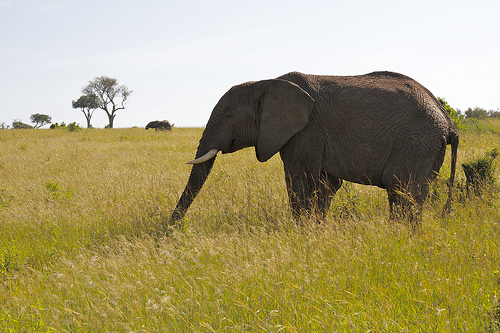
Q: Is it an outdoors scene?
A: Yes, it is outdoors.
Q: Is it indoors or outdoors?
A: It is outdoors.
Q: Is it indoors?
A: No, it is outdoors.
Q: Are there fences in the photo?
A: No, there are no fences.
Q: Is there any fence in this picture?
A: No, there are no fences.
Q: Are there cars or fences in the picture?
A: No, there are no fences or cars.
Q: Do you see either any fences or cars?
A: No, there are no fences or cars.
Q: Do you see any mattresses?
A: No, there are no mattresses.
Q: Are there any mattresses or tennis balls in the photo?
A: No, there are no mattresses or tennis balls.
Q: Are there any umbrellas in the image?
A: No, there are no umbrellas.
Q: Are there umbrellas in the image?
A: No, there are no umbrellas.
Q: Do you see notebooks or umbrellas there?
A: No, there are no umbrellas or notebooks.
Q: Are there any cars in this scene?
A: No, there are no cars.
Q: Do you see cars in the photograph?
A: No, there are no cars.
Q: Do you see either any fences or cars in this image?
A: No, there are no cars or fences.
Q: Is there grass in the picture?
A: Yes, there is grass.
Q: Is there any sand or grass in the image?
A: Yes, there is grass.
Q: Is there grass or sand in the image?
A: Yes, there is grass.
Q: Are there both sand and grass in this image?
A: No, there is grass but no sand.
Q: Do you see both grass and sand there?
A: No, there is grass but no sand.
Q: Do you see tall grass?
A: Yes, there is tall grass.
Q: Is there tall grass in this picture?
A: Yes, there is tall grass.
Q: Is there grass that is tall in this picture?
A: Yes, there is tall grass.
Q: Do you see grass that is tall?
A: Yes, there is grass that is tall.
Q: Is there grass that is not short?
A: Yes, there is tall grass.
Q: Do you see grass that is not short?
A: Yes, there is tall grass.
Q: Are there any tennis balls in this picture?
A: No, there are no tennis balls.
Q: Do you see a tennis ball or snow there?
A: No, there are no tennis balls or snow.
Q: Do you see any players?
A: No, there are no players.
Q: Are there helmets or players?
A: No, there are no players or helmets.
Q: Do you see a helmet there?
A: No, there are no helmets.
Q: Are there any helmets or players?
A: No, there are no helmets or players.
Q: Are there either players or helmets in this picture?
A: No, there are no helmets or players.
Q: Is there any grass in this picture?
A: Yes, there is grass.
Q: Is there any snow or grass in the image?
A: Yes, there is grass.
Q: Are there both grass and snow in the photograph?
A: No, there is grass but no snow.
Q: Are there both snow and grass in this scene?
A: No, there is grass but no snow.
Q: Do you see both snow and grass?
A: No, there is grass but no snow.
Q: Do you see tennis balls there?
A: No, there are no tennis balls.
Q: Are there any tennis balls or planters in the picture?
A: No, there are no tennis balls or planters.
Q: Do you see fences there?
A: No, there are no fences.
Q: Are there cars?
A: No, there are no cars.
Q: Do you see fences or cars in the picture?
A: No, there are no cars or fences.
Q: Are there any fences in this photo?
A: No, there are no fences.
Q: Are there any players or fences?
A: No, there are no fences or players.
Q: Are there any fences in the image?
A: No, there are no fences.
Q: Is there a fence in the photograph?
A: No, there are no fences.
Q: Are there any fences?
A: No, there are no fences.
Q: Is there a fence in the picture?
A: No, there are no fences.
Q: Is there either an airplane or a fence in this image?
A: No, there are no fences or airplanes.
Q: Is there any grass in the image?
A: Yes, there is grass.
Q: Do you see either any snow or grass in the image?
A: Yes, there is grass.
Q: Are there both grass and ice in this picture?
A: No, there is grass but no ice.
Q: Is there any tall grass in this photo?
A: Yes, there is tall grass.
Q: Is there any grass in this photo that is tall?
A: Yes, there is grass that is tall.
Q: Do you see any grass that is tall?
A: Yes, there is grass that is tall.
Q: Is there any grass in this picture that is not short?
A: Yes, there is tall grass.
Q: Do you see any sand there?
A: No, there is no sand.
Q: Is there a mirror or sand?
A: No, there are no sand or mirrors.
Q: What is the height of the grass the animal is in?
A: The grass is tall.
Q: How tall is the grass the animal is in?
A: The grass is tall.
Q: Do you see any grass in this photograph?
A: Yes, there is grass.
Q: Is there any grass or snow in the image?
A: Yes, there is grass.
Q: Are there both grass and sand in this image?
A: No, there is grass but no sand.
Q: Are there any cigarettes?
A: No, there are no cigarettes.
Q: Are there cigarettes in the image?
A: No, there are no cigarettes.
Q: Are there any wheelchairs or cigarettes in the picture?
A: No, there are no cigarettes or wheelchairs.